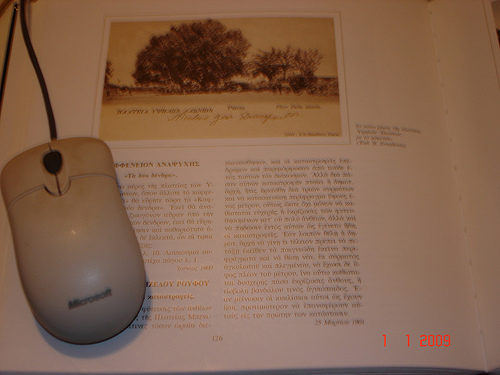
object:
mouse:
[1, 137, 147, 346]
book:
[0, 1, 499, 374]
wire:
[18, 0, 59, 142]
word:
[68, 288, 112, 310]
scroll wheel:
[43, 151, 62, 174]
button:
[49, 137, 118, 196]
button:
[0, 151, 60, 188]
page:
[2, 0, 487, 374]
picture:
[97, 17, 342, 142]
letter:
[177, 281, 182, 288]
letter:
[155, 162, 161, 168]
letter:
[204, 280, 209, 286]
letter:
[245, 188, 249, 193]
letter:
[323, 320, 330, 326]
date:
[383, 333, 451, 347]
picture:
[0, 1, 500, 374]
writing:
[116, 104, 320, 122]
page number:
[211, 335, 223, 342]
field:
[98, 76, 342, 136]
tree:
[132, 19, 253, 93]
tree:
[294, 48, 323, 76]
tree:
[105, 60, 115, 84]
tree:
[274, 49, 294, 80]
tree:
[244, 47, 284, 81]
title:
[114, 162, 200, 169]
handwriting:
[169, 109, 299, 122]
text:
[111, 158, 366, 329]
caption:
[355, 123, 420, 148]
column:
[114, 162, 214, 329]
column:
[223, 158, 365, 327]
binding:
[426, 1, 490, 373]